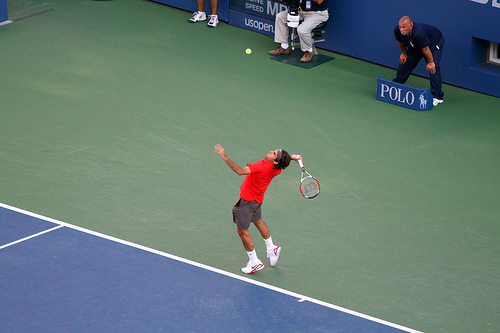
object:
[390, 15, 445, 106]
man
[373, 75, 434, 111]
sign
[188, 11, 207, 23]
tennis shoes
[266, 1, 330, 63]
man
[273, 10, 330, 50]
pants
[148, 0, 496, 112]
sidelines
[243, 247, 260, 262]
socks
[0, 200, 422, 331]
lines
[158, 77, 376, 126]
tennis court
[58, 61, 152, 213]
surface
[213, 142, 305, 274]
man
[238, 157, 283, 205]
t-shirt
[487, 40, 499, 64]
window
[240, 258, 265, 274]
shoes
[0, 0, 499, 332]
court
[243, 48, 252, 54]
ball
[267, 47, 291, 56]
loafers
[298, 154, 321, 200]
racket